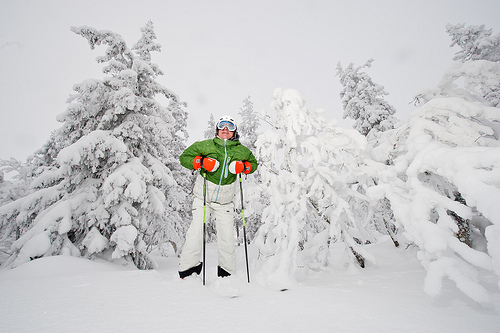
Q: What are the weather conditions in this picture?
A: It is overcast.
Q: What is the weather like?
A: It is overcast.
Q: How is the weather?
A: It is overcast.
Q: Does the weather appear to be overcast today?
A: Yes, it is overcast.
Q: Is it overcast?
A: Yes, it is overcast.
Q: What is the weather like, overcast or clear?
A: It is overcast.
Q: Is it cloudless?
A: No, it is overcast.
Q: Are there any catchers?
A: No, there are no catchers.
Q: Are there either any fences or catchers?
A: No, there are no catchers or fences.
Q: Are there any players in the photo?
A: No, there are no players.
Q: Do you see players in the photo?
A: No, there are no players.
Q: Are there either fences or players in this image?
A: No, there are no players or fences.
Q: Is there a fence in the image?
A: No, there are no fences.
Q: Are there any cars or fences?
A: No, there are no fences or cars.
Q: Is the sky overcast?
A: Yes, the sky is overcast.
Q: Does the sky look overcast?
A: Yes, the sky is overcast.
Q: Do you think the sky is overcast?
A: Yes, the sky is overcast.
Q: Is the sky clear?
A: No, the sky is overcast.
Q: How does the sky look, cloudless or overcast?
A: The sky is overcast.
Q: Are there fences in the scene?
A: No, there are no fences.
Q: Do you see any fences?
A: No, there are no fences.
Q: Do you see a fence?
A: No, there are no fences.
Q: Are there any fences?
A: No, there are no fences.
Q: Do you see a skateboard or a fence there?
A: No, there are no fences or skateboards.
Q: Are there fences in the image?
A: No, there are no fences.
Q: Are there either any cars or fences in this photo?
A: No, there are no fences or cars.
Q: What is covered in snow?
A: The tree is covered in snow.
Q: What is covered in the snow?
A: The tree is covered in snow.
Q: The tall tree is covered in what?
A: The tree is covered in snow.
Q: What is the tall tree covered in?
A: The tree is covered in snow.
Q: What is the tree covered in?
A: The tree is covered in snow.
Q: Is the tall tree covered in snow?
A: Yes, the tree is covered in snow.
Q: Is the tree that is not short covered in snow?
A: Yes, the tree is covered in snow.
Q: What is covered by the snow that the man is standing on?
A: The tree is covered by the snow.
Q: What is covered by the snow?
A: The tree is covered by the snow.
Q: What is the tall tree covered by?
A: The tree is covered by the snow.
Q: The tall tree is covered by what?
A: The tree is covered by the snow.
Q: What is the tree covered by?
A: The tree is covered by the snow.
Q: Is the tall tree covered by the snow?
A: Yes, the tree is covered by the snow.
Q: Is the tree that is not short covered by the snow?
A: Yes, the tree is covered by the snow.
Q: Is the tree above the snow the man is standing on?
A: Yes, the tree is above the snow.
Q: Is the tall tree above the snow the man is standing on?
A: Yes, the tree is above the snow.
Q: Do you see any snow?
A: Yes, there is snow.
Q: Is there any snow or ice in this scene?
A: Yes, there is snow.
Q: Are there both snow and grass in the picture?
A: No, there is snow but no grass.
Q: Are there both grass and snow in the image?
A: No, there is snow but no grass.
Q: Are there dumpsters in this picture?
A: No, there are no dumpsters.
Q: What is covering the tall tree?
A: The snow is covering the tree.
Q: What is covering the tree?
A: The snow is covering the tree.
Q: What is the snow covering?
A: The snow is covering the tree.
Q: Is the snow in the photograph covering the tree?
A: Yes, the snow is covering the tree.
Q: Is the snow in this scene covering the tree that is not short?
A: Yes, the snow is covering the tree.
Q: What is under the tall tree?
A: The snow is under the tree.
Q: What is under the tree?
A: The snow is under the tree.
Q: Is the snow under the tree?
A: Yes, the snow is under the tree.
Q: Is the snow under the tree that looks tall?
A: Yes, the snow is under the tree.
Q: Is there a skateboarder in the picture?
A: No, there are no skateboarders.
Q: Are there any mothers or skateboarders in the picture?
A: No, there are no skateboarders or mothers.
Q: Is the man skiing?
A: Yes, the man is skiing.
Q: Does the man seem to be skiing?
A: Yes, the man is skiing.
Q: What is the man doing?
A: The man is skiing.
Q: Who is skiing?
A: The man is skiing.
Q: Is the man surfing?
A: No, the man is skiing.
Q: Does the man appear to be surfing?
A: No, the man is skiing.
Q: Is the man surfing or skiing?
A: The man is skiing.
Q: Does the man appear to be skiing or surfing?
A: The man is skiing.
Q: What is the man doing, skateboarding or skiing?
A: The man is skiing.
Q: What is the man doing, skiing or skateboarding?
A: The man is skiing.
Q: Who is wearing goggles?
A: The man is wearing goggles.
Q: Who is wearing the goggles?
A: The man is wearing goggles.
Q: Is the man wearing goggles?
A: Yes, the man is wearing goggles.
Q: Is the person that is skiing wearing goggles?
A: Yes, the man is wearing goggles.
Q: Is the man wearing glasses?
A: No, the man is wearing goggles.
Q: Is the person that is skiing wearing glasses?
A: No, the man is wearing goggles.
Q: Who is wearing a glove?
A: The man is wearing a glove.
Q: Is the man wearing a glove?
A: Yes, the man is wearing a glove.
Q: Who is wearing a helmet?
A: The man is wearing a helmet.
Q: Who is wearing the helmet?
A: The man is wearing a helmet.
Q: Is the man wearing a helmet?
A: Yes, the man is wearing a helmet.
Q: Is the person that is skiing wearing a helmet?
A: Yes, the man is wearing a helmet.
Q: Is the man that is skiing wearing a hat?
A: No, the man is wearing a helmet.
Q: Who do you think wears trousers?
A: The man wears trousers.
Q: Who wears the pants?
A: The man wears trousers.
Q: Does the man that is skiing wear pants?
A: Yes, the man wears pants.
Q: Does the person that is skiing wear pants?
A: Yes, the man wears pants.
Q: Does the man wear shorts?
A: No, the man wears pants.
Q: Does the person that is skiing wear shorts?
A: No, the man wears pants.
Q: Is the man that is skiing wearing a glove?
A: Yes, the man is wearing a glove.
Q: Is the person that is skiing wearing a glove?
A: Yes, the man is wearing a glove.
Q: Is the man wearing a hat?
A: No, the man is wearing a glove.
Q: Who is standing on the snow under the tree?
A: The man is standing on the snow.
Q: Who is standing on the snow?
A: The man is standing on the snow.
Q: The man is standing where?
A: The man is standing on the snow.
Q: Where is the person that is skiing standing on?
A: The man is standing on the snow.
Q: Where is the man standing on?
A: The man is standing on the snow.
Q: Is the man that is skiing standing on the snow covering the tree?
A: Yes, the man is standing on the snow.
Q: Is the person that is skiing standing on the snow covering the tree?
A: Yes, the man is standing on the snow.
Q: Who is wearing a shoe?
A: The man is wearing a shoe.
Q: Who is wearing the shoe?
A: The man is wearing a shoe.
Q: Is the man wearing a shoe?
A: Yes, the man is wearing a shoe.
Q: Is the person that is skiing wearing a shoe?
A: Yes, the man is wearing a shoe.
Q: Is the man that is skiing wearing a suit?
A: No, the man is wearing a shoe.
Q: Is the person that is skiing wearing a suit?
A: No, the man is wearing a shoe.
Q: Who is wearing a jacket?
A: The man is wearing a jacket.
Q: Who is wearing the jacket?
A: The man is wearing a jacket.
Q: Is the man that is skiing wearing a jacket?
A: Yes, the man is wearing a jacket.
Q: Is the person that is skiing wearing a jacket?
A: Yes, the man is wearing a jacket.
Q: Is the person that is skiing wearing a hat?
A: No, the man is wearing a jacket.